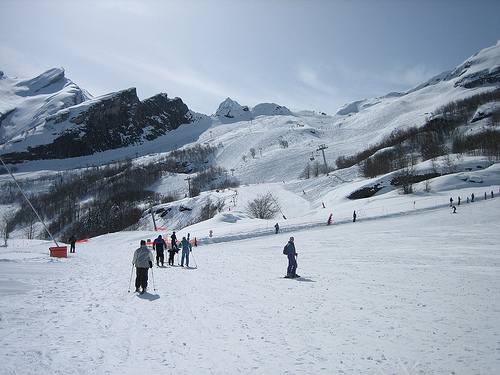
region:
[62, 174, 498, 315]
people on a ski resort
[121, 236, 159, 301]
skier wears a white coat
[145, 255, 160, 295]
a snow pole on right hand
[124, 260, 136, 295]
a snow pole on left hand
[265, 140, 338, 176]
snow lift is over the hill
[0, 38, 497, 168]
mountains cover with snow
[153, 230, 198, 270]
two adults and a kid on a hill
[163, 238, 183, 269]
a kid holding two snow poles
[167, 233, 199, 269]
a woman on right side of kid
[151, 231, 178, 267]
a man on left side of kid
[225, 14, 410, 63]
this is the sky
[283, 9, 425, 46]
the sky is blue in color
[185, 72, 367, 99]
these are the clouds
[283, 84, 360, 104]
the clouds are white in color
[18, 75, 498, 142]
these are the hills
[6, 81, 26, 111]
the hills are covered with snow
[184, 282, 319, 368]
this is the ground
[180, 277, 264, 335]
the ground is full of snow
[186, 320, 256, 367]
the snow is white in color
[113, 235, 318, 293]
these are several people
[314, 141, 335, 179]
tower holding a ski lift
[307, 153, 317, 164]
gondola on a ski lift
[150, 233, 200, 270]
two adults skiing with a child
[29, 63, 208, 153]
snowcapped mountain peaks near a ski area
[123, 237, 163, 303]
an adult getting ready to ski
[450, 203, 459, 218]
a skier going downhill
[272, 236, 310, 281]
a skier resting on the snow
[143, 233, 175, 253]
orange safety fencing at a ski area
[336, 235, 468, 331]
snow on the ground in a ski area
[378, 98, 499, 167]
trees on a hillside near a ski area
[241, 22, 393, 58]
this is the sky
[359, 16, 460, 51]
the sky is blue in color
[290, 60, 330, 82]
these are the clouds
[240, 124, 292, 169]
this is a snow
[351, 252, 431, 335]
the snow is white in color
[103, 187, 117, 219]
this is a tree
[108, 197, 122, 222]
the tree has green leaves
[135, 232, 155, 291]
this is a man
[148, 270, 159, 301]
this is a stick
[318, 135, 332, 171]
this is a pole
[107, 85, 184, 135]
Rock cliff on a mountainside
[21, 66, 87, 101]
Snowcapped mountain top at ski resort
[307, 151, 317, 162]
Gondola on ski lift at ski resort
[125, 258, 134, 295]
Ski poles being held by skier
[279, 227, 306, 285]
Skier traveling across the snow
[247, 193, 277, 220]
Tree in the middle of the ski area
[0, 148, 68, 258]
Support for something that's out of frame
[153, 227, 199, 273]
Group of skiers on mountainside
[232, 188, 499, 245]
Trail worn in snow by people on tow rope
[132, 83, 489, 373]
Mountainside of ski resort